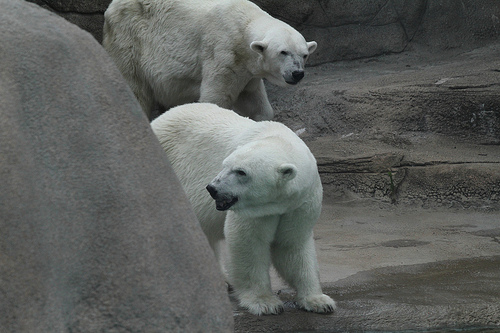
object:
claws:
[234, 283, 337, 316]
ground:
[232, 200, 499, 332]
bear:
[150, 102, 337, 316]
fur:
[129, 0, 201, 97]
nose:
[292, 68, 305, 80]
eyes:
[235, 169, 247, 177]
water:
[234, 254, 500, 331]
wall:
[253, 0, 500, 55]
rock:
[0, 0, 237, 333]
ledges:
[273, 78, 500, 203]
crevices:
[318, 161, 500, 177]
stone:
[275, 96, 355, 155]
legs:
[196, 69, 273, 123]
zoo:
[2, 0, 500, 333]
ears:
[250, 41, 268, 56]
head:
[250, 26, 318, 86]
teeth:
[216, 197, 237, 208]